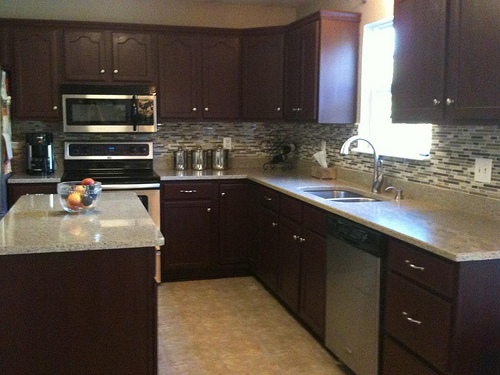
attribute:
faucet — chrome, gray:
[335, 135, 386, 189]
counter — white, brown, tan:
[4, 193, 167, 247]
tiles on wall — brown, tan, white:
[155, 124, 348, 153]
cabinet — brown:
[3, 28, 353, 117]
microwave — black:
[62, 95, 161, 129]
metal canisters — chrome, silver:
[177, 146, 230, 169]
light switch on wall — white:
[477, 157, 492, 178]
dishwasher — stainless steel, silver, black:
[318, 228, 386, 369]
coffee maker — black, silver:
[26, 132, 51, 170]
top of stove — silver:
[71, 162, 160, 176]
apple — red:
[80, 178, 96, 186]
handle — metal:
[178, 189, 201, 196]